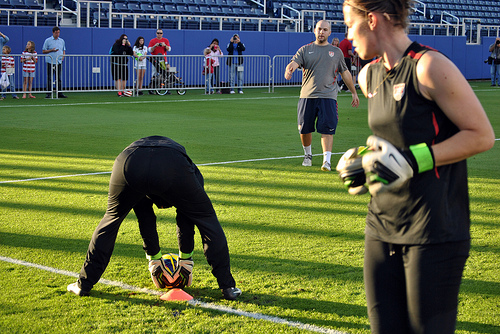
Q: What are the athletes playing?
A: Soccer.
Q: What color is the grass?
A: Green.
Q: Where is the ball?
A: On the grass.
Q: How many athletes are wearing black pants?
A: Two.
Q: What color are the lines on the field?
A: White.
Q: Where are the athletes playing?
A: On a soccer field.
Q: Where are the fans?
A: Behind the fence.